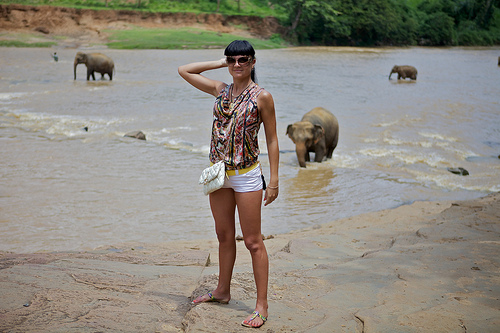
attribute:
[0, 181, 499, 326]
ground — soil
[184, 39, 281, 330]
woman — posing 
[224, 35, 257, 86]
hair — black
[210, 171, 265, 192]
shorts — white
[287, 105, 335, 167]
elephant — small, walking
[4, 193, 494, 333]
sand — light brown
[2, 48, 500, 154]
water — calm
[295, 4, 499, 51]
trees — green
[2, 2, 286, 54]
bank — brown, green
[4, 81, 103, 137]
wave — white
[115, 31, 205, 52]
grass — green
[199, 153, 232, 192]
handbag — white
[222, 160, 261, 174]
belt — yellow